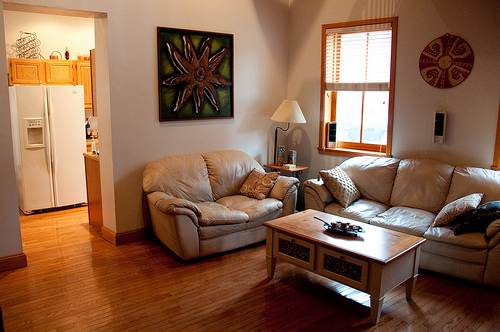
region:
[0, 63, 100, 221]
White refrigerator in kitchen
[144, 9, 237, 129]
Star painting on wall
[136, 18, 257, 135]
Red, orange, and green painting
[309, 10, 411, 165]
Wooden window frame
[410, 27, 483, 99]
Orange and yellow decoration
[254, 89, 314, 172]
White lamp on desk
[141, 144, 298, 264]
Small beige couch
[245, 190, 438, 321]
Brown coffee table in living room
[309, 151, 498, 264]
Three pillows on couch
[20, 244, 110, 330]
Light brown wood floor.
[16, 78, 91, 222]
White two door fridge.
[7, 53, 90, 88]
Storage space above the fridge.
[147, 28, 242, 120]
Large picture above the love seat.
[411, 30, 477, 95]
Round wall hanging above the couch.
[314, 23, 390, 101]
Mini blind on the window.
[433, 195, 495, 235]
Two pillows on the couch.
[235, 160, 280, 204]
One pillow on the love seat.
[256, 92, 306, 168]
Lamp on the end table.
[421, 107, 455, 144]
Speaker above the couch.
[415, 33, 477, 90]
Round brown and tan decoration on wall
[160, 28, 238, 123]
Brown and green decoration on wall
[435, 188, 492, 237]
Two square throw pillows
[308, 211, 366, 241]
Leaf shaped tray on coffee table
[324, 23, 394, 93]
Open mini blinds in window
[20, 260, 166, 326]
Shiny wood floor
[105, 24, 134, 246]
White wall with wood base board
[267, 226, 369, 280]
Wood coffee table with two drop down drawers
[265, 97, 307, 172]
square end table with attached lamp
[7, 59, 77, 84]
Wood cabinets above refrigerator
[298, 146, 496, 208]
Cream leather sofa with three decorative pillow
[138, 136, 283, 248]
cream leather loveseat with pillow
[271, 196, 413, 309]
wooden center table with decoration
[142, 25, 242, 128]
painting decoration on the side of the wall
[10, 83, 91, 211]
white two door refrigerator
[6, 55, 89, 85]
light brown cabinets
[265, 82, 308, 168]
stand alone lamps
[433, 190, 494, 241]
two decorative pillows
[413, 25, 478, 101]
round wall decoration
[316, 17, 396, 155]
white window blinds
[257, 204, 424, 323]
Brown coffee table in the room.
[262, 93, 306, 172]
Table lamp in the corner.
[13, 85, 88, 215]
White refrigerator in the background.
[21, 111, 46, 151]
Water and ice dispenser on the door.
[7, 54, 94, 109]
Brown kitchen cabinets in the background.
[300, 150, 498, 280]
Beige couch by the wall.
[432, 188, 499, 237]
Pillows on the couch.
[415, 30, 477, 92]
Circle wall decoration.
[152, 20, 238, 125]
Picture on the wall.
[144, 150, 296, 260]
Beige loveseat against the wall.